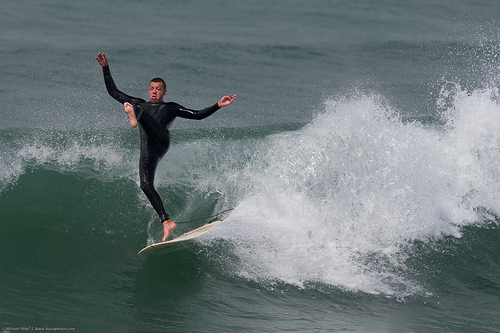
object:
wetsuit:
[102, 63, 226, 227]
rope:
[172, 207, 235, 224]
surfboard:
[138, 218, 236, 255]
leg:
[124, 101, 169, 150]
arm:
[101, 67, 145, 104]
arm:
[172, 102, 220, 122]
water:
[1, 244, 135, 332]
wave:
[242, 87, 500, 299]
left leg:
[138, 149, 176, 242]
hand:
[94, 51, 110, 66]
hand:
[217, 93, 236, 107]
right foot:
[123, 101, 139, 130]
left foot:
[161, 220, 176, 240]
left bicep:
[179, 105, 195, 115]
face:
[147, 81, 165, 99]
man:
[95, 50, 239, 242]